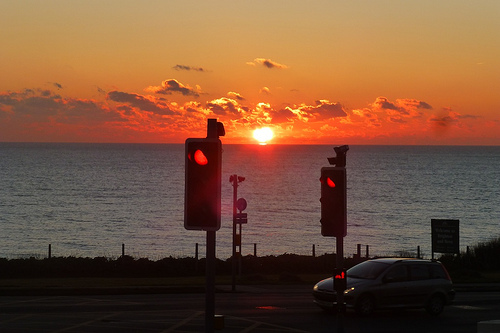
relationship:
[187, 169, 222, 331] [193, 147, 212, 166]
metal under light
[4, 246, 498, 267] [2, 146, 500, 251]
fence next to ocean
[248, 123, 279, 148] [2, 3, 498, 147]
sun in sky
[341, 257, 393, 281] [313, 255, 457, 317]
windshield on car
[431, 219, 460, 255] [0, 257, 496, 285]
sign next to beach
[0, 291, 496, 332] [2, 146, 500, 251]
road next to ocean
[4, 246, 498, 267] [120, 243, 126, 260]
fence has post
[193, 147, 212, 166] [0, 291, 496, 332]
light next to road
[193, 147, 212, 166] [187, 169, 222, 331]
light inside of metal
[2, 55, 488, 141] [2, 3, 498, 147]
clouds in sky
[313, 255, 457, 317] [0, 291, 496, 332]
car on road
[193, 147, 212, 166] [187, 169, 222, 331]
light on metal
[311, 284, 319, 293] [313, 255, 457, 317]
light on car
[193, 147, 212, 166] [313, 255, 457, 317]
light on car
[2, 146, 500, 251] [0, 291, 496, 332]
ocean near road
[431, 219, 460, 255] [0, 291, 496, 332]
sign near road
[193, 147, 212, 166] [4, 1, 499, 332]
light in scene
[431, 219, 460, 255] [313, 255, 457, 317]
sign behind car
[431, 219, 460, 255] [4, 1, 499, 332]
sign behind scene